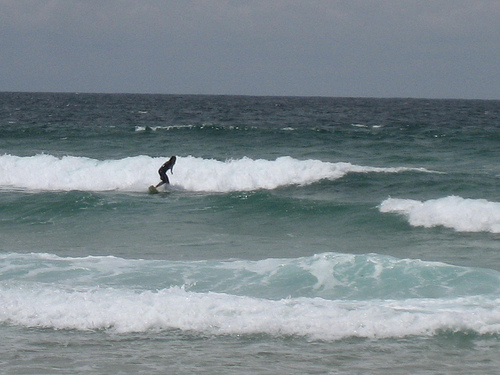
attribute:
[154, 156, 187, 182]
man — surfing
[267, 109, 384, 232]
water — blue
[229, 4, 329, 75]
sky — clear, blue